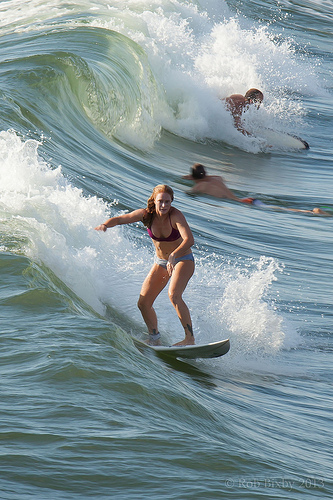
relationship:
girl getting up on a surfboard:
[93, 184, 195, 347] [128, 333, 232, 362]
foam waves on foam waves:
[0, 128, 288, 368] [0, 128, 288, 368]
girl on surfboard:
[122, 169, 204, 339] [115, 302, 265, 377]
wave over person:
[0, 2, 262, 484] [219, 88, 274, 148]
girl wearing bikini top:
[93, 184, 195, 347] [146, 208, 194, 270]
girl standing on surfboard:
[93, 184, 195, 347] [146, 336, 228, 357]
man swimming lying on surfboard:
[163, 162, 333, 217] [259, 205, 312, 214]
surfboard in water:
[259, 205, 312, 214] [0, 0, 332, 498]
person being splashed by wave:
[219, 88, 274, 148] [70, 0, 301, 159]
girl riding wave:
[93, 184, 195, 347] [0, 1, 322, 485]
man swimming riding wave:
[163, 162, 333, 217] [0, 1, 322, 485]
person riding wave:
[219, 88, 274, 148] [0, 1, 322, 485]